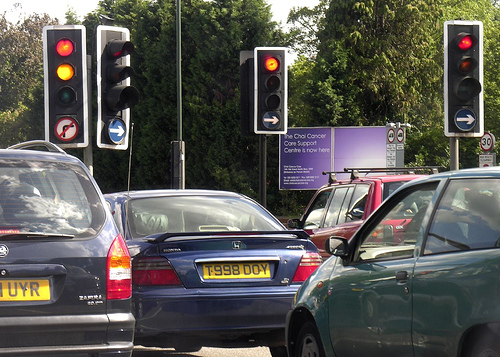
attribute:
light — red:
[454, 33, 476, 51]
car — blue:
[102, 188, 327, 349]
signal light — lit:
[41, 22, 91, 150]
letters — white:
[282, 132, 328, 187]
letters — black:
[1, 279, 55, 303]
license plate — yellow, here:
[200, 261, 273, 280]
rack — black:
[317, 165, 444, 187]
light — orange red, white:
[104, 232, 136, 303]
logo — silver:
[0, 244, 12, 259]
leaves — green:
[84, 0, 277, 208]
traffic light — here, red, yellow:
[42, 22, 92, 149]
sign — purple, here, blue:
[278, 124, 409, 190]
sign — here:
[478, 129, 496, 150]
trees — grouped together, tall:
[2, 0, 499, 221]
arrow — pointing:
[109, 117, 127, 143]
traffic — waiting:
[0, 137, 499, 357]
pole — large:
[167, 2, 189, 190]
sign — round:
[54, 116, 79, 144]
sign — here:
[452, 108, 478, 134]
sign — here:
[262, 112, 282, 129]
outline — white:
[96, 23, 133, 152]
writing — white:
[280, 132, 330, 188]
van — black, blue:
[0, 139, 137, 352]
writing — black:
[203, 261, 270, 278]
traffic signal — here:
[41, 24, 91, 152]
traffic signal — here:
[92, 23, 135, 153]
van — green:
[281, 167, 498, 357]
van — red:
[290, 165, 437, 261]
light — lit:
[38, 28, 89, 152]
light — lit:
[235, 39, 301, 145]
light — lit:
[426, 15, 496, 152]